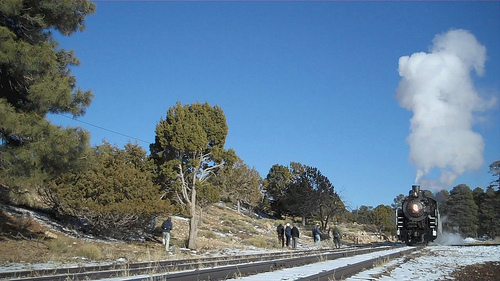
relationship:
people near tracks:
[327, 223, 345, 249] [0, 242, 422, 280]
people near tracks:
[311, 223, 325, 243] [0, 242, 422, 280]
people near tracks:
[290, 223, 303, 251] [0, 242, 422, 280]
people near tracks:
[281, 220, 294, 250] [0, 242, 422, 280]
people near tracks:
[273, 220, 286, 250] [0, 242, 422, 280]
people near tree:
[311, 223, 325, 243] [273, 168, 354, 237]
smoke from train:
[387, 22, 497, 189] [391, 179, 446, 249]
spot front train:
[412, 200, 423, 215] [391, 179, 446, 249]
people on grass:
[327, 223, 345, 249] [1, 182, 376, 275]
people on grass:
[311, 223, 325, 243] [1, 182, 376, 275]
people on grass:
[290, 223, 303, 251] [1, 182, 376, 275]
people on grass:
[281, 220, 294, 250] [1, 182, 376, 275]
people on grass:
[273, 220, 286, 250] [1, 182, 376, 275]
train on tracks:
[391, 179, 446, 249] [0, 242, 422, 280]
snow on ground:
[392, 234, 497, 280] [1, 242, 499, 280]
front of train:
[393, 184, 433, 241] [391, 179, 446, 249]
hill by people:
[1, 173, 333, 273] [327, 223, 345, 249]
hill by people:
[1, 173, 333, 273] [311, 223, 325, 243]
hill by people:
[1, 173, 333, 273] [290, 223, 303, 251]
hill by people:
[1, 173, 333, 273] [281, 220, 294, 250]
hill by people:
[1, 173, 333, 273] [273, 220, 286, 250]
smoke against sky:
[387, 22, 497, 189] [1, 0, 499, 211]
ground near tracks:
[1, 242, 499, 280] [0, 242, 422, 280]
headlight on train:
[410, 202, 420, 215] [391, 179, 446, 249]